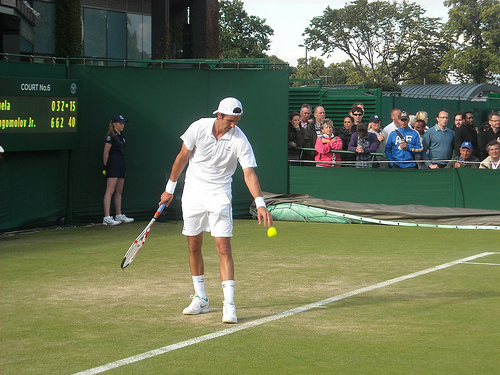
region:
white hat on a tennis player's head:
[208, 94, 248, 116]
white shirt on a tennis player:
[176, 96, 261, 208]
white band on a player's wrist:
[165, 180, 182, 196]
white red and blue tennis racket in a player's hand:
[116, 199, 170, 270]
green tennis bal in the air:
[264, 224, 281, 239]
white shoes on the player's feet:
[180, 293, 248, 323]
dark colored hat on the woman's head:
[111, 109, 130, 124]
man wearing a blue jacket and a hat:
[388, 109, 426, 166]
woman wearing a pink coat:
[311, 116, 345, 165]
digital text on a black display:
[1, 99, 79, 129]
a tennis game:
[2, 4, 498, 369]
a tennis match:
[7, 3, 498, 371]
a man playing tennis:
[112, 87, 290, 335]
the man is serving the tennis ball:
[108, 84, 308, 332]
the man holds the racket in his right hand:
[110, 91, 279, 330]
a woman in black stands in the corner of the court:
[96, 107, 150, 232]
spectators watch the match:
[289, 94, 498, 181]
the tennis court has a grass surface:
[3, 217, 496, 371]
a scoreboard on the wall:
[1, 71, 88, 158]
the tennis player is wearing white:
[113, 93, 291, 329]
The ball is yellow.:
[264, 222, 281, 244]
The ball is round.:
[263, 215, 288, 245]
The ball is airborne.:
[253, 214, 288, 249]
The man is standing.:
[118, 89, 296, 342]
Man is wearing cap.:
[108, 85, 301, 329]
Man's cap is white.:
[100, 86, 298, 337]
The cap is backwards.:
[110, 85, 285, 340]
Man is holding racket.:
[108, 87, 296, 342]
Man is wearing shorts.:
[114, 93, 286, 330]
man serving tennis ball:
[117, 92, 303, 338]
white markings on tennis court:
[298, 259, 473, 321]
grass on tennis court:
[293, 230, 382, 283]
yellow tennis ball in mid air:
[257, 224, 289, 243]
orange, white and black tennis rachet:
[113, 205, 166, 287]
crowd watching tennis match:
[298, 92, 494, 178]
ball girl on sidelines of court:
[91, 107, 143, 229]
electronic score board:
[4, 70, 85, 167]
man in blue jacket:
[383, 108, 424, 173]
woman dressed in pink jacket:
[307, 119, 346, 176]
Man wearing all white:
[144, 88, 278, 333]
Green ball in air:
[252, 217, 294, 254]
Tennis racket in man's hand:
[113, 191, 171, 276]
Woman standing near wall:
[92, 110, 137, 240]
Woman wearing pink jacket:
[310, 119, 346, 177]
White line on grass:
[269, 259, 398, 339]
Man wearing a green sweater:
[422, 110, 454, 170]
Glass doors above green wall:
[56, 7, 173, 76]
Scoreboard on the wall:
[0, 75, 93, 155]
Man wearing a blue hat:
[440, 142, 480, 178]